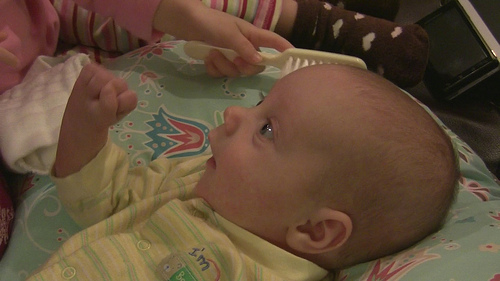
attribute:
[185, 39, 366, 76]
brush — white, held, plastic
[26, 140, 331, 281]
pajamas — yellow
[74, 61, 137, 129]
hand — up, fisted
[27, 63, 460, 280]
baby — looking, existing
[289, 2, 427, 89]
sock — brown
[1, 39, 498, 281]
pillow — blue, green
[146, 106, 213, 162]
flower — blue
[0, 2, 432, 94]
kid — brushing, combing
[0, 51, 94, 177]
towel — small